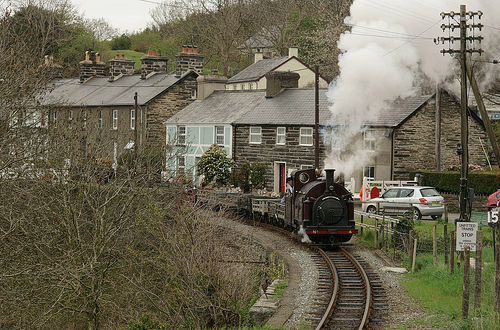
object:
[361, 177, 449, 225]
car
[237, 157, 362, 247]
train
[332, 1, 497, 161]
steam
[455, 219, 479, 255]
white sign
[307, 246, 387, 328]
tracks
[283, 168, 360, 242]
frontcar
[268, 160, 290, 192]
door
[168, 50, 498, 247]
house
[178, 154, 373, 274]
train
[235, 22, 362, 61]
building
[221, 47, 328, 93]
building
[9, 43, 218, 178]
building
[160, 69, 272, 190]
building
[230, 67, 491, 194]
building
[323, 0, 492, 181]
steam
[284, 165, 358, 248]
train engine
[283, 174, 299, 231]
someone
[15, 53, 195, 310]
trees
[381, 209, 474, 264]
ground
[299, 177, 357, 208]
oven rack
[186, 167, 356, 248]
train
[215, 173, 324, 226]
cars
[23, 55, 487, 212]
houses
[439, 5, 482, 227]
telephone pole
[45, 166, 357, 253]
train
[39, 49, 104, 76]
chimneys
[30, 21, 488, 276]
buildings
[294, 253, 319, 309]
rocks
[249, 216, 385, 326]
tracks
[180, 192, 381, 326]
tracks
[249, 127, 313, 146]
windows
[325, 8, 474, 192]
cloud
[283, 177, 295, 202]
person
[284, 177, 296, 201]
engineer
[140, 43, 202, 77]
chimneys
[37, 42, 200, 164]
houses